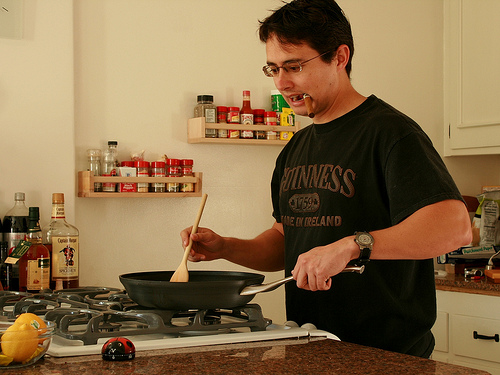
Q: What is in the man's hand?
A: Spoon.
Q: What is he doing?
A: Cooking.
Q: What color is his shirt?
A: Black.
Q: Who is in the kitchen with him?
A: No one.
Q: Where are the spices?
A: On the spice rack on the wall.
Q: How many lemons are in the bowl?
A: Two.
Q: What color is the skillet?
A: Black.